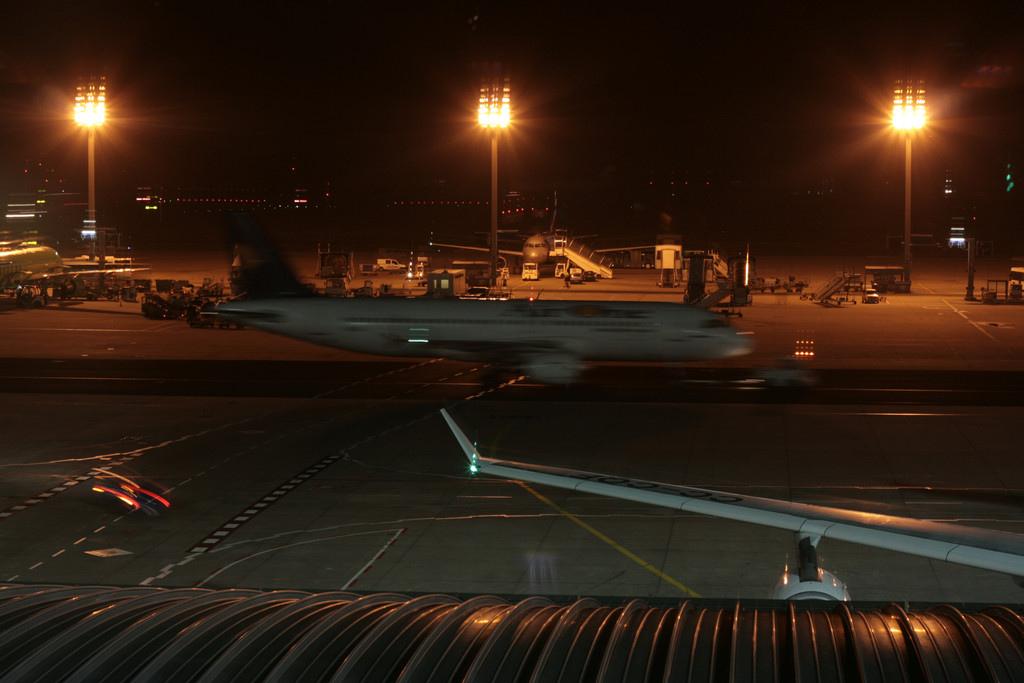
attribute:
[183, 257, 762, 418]
plane — large, white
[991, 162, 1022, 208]
light — green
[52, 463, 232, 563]
stand — orange, white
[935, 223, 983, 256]
sign — white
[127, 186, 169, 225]
sign — red, white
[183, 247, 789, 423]
airplane — white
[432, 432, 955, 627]
wing — white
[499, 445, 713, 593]
stripe — yellow , Solid 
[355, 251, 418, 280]
van — white